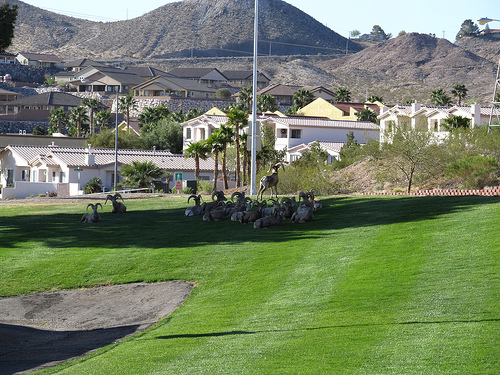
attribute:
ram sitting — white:
[181, 191, 210, 220]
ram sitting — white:
[222, 189, 249, 221]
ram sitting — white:
[102, 189, 131, 219]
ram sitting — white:
[76, 198, 107, 228]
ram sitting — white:
[294, 189, 329, 220]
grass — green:
[338, 197, 395, 243]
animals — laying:
[176, 188, 324, 235]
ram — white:
[83, 202, 103, 222]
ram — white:
[103, 193, 127, 213]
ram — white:
[254, 157, 285, 200]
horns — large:
[78, 189, 129, 214]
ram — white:
[291, 200, 317, 224]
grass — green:
[253, 247, 461, 352]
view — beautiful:
[3, 1, 499, 367]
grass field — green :
[179, 223, 345, 283]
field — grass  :
[2, 187, 497, 374]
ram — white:
[292, 173, 314, 235]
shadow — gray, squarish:
[1, 308, 166, 373]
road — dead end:
[0, 278, 187, 373]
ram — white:
[183, 193, 204, 217]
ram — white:
[290, 190, 315, 222]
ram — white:
[253, 201, 285, 227]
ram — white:
[202, 200, 232, 222]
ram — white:
[229, 197, 257, 222]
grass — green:
[3, 195, 498, 373]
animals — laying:
[85, 154, 334, 234]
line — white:
[157, 192, 491, 373]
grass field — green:
[116, 221, 420, 282]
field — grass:
[3, 195, 484, 367]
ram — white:
[104, 190, 133, 218]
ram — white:
[208, 187, 228, 208]